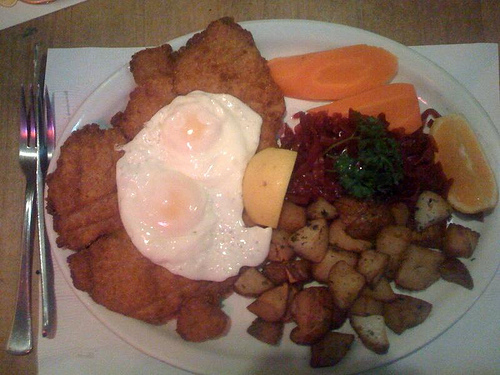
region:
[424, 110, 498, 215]
orange slice on plate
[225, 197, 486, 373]
herbed home potatoes on plate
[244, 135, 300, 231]
wedge of lemon on plate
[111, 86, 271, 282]
eggs cooked overeasy on childen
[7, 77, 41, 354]
silver fork left of plate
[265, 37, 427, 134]
sliced carrots on plate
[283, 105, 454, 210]
homemade salsa on potatoes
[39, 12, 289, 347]
chicken fried chicked with eggs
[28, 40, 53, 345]
silver knife on top of fork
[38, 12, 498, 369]
large country meal with veggies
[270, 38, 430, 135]
carrots sliced long ways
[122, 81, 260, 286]
two eggs fried to order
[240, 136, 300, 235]
lemon wedge used as garnish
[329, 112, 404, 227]
parsley used as garnish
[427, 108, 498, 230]
orange wedge used as garnish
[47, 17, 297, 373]
chicken fried meat on plate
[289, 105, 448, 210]
red relish on white plate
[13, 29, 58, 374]
silver knife and fork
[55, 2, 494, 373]
large glass white plate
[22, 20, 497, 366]
white paper place mat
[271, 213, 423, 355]
Cooked potatoes on a plate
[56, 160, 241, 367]
Brown food on a plate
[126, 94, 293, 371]
Fried eggs on a plate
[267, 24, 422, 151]
Carrots on a plate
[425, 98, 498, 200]
Orange slice on a plate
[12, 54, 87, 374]
Fork and knife by a plate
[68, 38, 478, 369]
Breakfast on a plate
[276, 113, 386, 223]
Red food on a plate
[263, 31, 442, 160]
Orange vegetable on a plate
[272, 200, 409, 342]
Spices on potatoes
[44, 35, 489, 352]
food on a plate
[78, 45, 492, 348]
food on a white plate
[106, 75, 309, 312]
fried eggs on a plate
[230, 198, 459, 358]
fried potatos on a plate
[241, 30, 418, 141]
carrots on a plate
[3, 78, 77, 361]
A knife and fork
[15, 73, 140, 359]
A knife and fork next to a plate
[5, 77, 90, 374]
A knife on top of a fork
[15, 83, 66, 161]
tines on a fork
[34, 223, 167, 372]
the edge of a plate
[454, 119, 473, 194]
this is a sliced orange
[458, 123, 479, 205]
the orange is tasty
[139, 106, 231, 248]
this is a milk poured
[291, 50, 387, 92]
this is a piece of sliced mango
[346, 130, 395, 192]
the veges are few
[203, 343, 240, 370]
this is a plate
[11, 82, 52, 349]
a fork and a knife are beside the plate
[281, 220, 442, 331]
the beef are sliced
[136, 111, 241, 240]
the milk is white in color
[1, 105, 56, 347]
the knife and fork are shiny